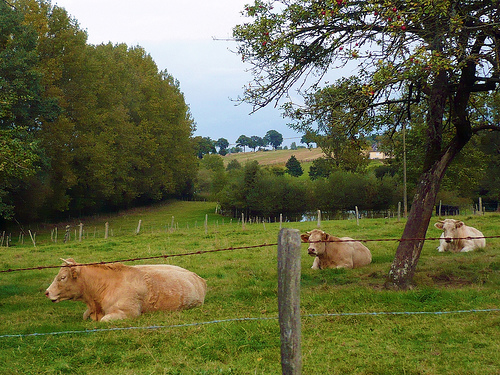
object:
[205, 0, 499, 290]
tree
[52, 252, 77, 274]
horn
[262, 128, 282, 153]
tree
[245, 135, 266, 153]
tree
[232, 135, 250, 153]
tree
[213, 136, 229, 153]
tree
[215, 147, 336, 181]
hillside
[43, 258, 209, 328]
cow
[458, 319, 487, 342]
grass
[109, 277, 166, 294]
fur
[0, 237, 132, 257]
grass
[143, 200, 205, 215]
ground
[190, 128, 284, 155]
trees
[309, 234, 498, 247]
barb wire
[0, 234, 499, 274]
wire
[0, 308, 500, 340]
wire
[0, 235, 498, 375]
fence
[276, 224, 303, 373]
post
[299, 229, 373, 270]
cows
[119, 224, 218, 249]
field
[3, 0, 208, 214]
tree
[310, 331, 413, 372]
grass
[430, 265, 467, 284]
ground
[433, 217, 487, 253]
cow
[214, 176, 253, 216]
bush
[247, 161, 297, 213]
bush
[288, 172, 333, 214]
bush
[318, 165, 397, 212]
bush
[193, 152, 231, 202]
bush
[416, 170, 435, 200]
bark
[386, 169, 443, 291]
tree trunk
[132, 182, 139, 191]
leaves